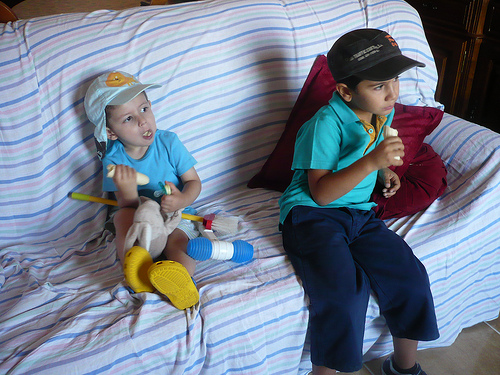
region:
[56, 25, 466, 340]
two children sitting on a couch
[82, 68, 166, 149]
a white hat with a goldfish on it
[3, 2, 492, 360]
couch covered with a blanket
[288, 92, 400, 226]
a teal blue collared childs shirt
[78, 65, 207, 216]
a young child holding a banana in right hand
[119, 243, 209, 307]
a pair of yellow rubber shoes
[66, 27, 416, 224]
two kids wearing teal colored shirts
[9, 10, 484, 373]
white with blue, pink and grey stripes covering couch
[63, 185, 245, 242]
a yellow, red and white play broom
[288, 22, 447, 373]
a young boy wearing high water pants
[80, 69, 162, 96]
Hat with a fish on it the girl is wearing.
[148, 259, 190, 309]
Yellow shoes the little girl is wearing.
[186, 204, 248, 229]
Toy broom the little girl has.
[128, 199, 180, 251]
Toy rabbit the little girl has.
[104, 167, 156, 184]
Banana the girl is eating.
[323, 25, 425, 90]
Hat the little boy is wearing.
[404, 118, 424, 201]
Pillows the boy is leaning on.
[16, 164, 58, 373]
Sheet over the couch.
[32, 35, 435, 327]
Couch the kids are sitting on.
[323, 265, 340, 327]
Jeans the boy is wearing.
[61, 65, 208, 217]
Little boy eating a banana and looking over to the left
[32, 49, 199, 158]
Little boy with with cap on and yellow whale on the front of cap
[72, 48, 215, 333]
Little boy with yellow Croc's on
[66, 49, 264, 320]
Little boy holding a banana in his right hand and toy bunny on his lap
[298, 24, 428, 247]
Little boy with black cap holding a half eaten banana in his right hand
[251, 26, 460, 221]
Little boy leaning on two red pillows while sitting on a couch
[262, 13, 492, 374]
Little boy sitting on a couch covered with a striped sheet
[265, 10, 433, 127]
Little boy wearing a black cap with a logo on the front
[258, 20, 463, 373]
Little boy wearing dark blue pants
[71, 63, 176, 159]
Little boy chewing on banana with mouth open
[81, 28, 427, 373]
two kids sit on a couch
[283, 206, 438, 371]
the boy is wearing navy pants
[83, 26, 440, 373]
the boys are eating bananas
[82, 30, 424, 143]
the boys are wearing hats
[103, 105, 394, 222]
the boys are wearing blue shirts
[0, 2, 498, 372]
the couch has a blanket over it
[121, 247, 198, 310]
the little boy is wearing yellow shoes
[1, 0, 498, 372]
the blanket is striped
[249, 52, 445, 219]
the pillow is red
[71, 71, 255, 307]
the boy is holding toys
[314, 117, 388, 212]
the shirt is green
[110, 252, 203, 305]
the fliplops are yellow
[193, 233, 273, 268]
the toy is blue and white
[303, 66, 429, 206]
the pillow is red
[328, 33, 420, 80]
the cape is black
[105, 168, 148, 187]
the banana is half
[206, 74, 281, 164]
the sheet has blue stripes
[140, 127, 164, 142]
the mouth is full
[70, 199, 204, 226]
the broom is yellow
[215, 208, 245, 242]
the bristles are white